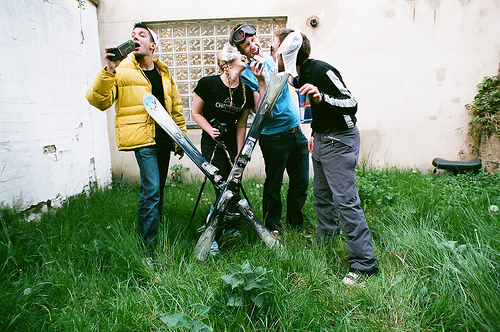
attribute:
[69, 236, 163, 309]
grass — green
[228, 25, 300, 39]
goggles — black, ski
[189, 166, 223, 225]
pole — long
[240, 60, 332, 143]
shirt — blue, tee, worn, black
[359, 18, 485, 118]
wall — white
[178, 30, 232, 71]
window — glass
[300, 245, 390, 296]
shoes — tennis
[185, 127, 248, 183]
pants — black, worn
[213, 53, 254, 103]
hair — braided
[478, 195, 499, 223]
flower — small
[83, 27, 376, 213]
people — standing, grouped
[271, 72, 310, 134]
man — lifting, wearing, drinking, holding, standing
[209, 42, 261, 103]
woman — laughing, holding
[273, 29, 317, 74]
brassiere — white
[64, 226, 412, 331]
yard — overgrown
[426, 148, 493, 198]
seat — black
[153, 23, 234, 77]
tiles — set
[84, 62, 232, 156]
jacket — yellow, worn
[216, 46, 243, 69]
hat — white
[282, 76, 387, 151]
sweater — black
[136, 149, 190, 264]
jeans — blue, worn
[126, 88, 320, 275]
skis — x